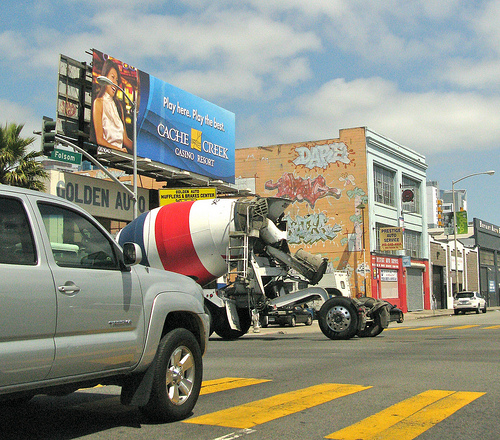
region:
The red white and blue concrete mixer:
[115, 195, 240, 290]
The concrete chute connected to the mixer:
[266, 230, 332, 286]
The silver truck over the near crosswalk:
[1, 183, 211, 425]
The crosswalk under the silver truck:
[76, 373, 491, 438]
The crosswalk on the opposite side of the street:
[384, 316, 497, 333]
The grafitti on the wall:
[259, 140, 366, 281]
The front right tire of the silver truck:
[141, 320, 206, 421]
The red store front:
[371, 252, 433, 317]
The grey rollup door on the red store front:
[403, 260, 428, 314]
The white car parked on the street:
[451, 287, 487, 320]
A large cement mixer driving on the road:
[122, 179, 405, 332]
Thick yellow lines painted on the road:
[221, 382, 454, 439]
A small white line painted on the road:
[211, 423, 255, 439]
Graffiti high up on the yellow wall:
[260, 140, 364, 240]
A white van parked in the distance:
[450, 286, 495, 313]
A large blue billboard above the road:
[70, 53, 246, 185]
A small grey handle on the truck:
[60, 277, 82, 300]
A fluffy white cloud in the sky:
[290, 76, 475, 154]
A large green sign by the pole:
[457, 208, 469, 235]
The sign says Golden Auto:
[49, 175, 156, 216]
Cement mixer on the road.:
[100, 193, 401, 344]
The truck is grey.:
[3, 177, 212, 421]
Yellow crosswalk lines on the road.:
[85, 354, 495, 439]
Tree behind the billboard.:
[0, 118, 53, 193]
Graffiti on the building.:
[267, 143, 368, 257]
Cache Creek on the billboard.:
[151, 118, 247, 161]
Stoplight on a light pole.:
[31, 71, 150, 212]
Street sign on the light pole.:
[36, 140, 87, 170]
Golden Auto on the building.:
[42, 169, 154, 219]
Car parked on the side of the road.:
[439, 277, 499, 321]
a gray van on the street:
[1, 180, 213, 417]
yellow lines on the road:
[177, 364, 491, 436]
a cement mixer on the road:
[136, 178, 393, 349]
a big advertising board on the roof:
[39, 56, 244, 196]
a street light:
[443, 160, 498, 275]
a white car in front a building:
[420, 258, 491, 319]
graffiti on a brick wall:
[279, 133, 366, 257]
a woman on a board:
[80, 52, 153, 152]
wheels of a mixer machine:
[220, 289, 394, 344]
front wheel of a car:
[140, 320, 212, 417]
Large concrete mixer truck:
[106, 188, 406, 345]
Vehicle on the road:
[0, 176, 217, 432]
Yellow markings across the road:
[62, 363, 494, 438]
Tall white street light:
[446, 151, 498, 321]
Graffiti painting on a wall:
[262, 129, 361, 251]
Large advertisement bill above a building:
[87, 107, 243, 192]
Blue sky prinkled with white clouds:
[0, 0, 496, 223]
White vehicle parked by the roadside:
[448, 287, 490, 317]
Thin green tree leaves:
[0, 112, 55, 197]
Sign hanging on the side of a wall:
[376, 223, 408, 257]